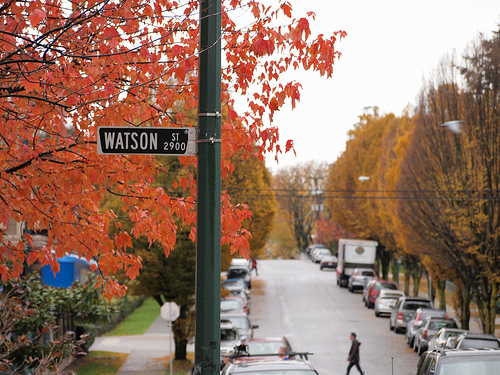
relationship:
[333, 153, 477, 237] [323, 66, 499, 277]
leaves are on trees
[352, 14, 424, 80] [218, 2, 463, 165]
clouds are in sky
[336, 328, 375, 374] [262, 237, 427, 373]
man crossing street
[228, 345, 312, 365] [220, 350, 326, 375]
rack on a car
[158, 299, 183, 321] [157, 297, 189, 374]
back of stop sign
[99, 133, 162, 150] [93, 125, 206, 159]
watson on sign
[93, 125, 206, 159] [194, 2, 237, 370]
sign on pole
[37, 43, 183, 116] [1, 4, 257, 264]
leaves are on tree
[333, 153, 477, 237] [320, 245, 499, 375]
leaves are by cars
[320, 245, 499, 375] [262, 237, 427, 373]
cars are in street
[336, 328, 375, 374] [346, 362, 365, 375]
man wearing pants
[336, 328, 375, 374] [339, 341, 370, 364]
man wearing a jacket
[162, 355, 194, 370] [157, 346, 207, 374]
dead leaves are on ground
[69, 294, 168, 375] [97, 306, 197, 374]
grass by sidewalk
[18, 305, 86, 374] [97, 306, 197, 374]
fencing by sidewalk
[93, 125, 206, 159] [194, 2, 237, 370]
sign on a pole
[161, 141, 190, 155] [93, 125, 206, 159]
2900 block on sign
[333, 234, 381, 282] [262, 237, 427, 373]
box truck on street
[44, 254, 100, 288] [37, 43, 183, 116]
object behind leaves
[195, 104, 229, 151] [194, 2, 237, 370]
clamp on pole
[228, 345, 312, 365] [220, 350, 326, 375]
rack on car